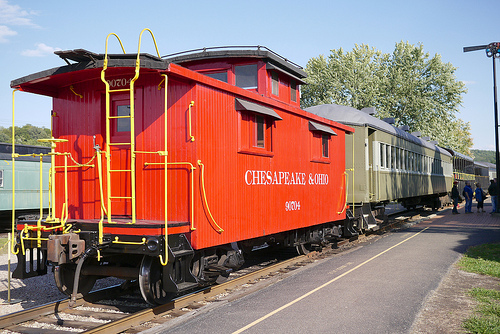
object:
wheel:
[122, 241, 184, 312]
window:
[253, 111, 265, 151]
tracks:
[0, 200, 480, 332]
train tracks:
[0, 200, 456, 332]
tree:
[285, 42, 474, 159]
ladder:
[96, 25, 159, 213]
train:
[6, 27, 496, 308]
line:
[230, 221, 430, 331]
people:
[441, 162, 498, 228]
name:
[244, 163, 333, 187]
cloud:
[0, 18, 18, 52]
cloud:
[1, 6, 42, 28]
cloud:
[17, 36, 59, 59]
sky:
[0, 3, 498, 150]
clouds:
[22, 41, 70, 56]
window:
[114, 104, 129, 131]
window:
[269, 74, 277, 96]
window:
[290, 83, 296, 101]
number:
[283, 199, 301, 211]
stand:
[16, 150, 176, 243]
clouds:
[222, 14, 254, 36]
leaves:
[316, 47, 402, 122]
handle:
[178, 100, 202, 142]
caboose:
[0, 37, 373, 304]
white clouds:
[0, 0, 48, 49]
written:
[242, 167, 308, 187]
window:
[232, 65, 260, 93]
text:
[240, 164, 333, 189]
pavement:
[135, 220, 478, 330]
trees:
[321, 62, 445, 127]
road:
[162, 203, 485, 323]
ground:
[15, 200, 485, 325]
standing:
[460, 210, 498, 266]